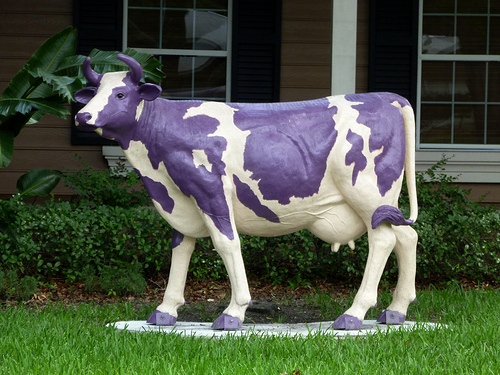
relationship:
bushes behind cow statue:
[11, 15, 82, 115] [64, 44, 435, 343]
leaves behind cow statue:
[11, 15, 82, 115] [64, 44, 435, 343]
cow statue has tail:
[64, 44, 435, 343] [398, 94, 424, 227]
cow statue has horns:
[64, 44, 435, 343] [77, 49, 148, 81]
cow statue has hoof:
[64, 44, 435, 343] [208, 310, 248, 335]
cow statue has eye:
[64, 44, 435, 343] [115, 87, 127, 104]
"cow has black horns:
[64, 44, 435, 343] [77, 49, 148, 81]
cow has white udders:
[64, 44, 435, 343] [306, 204, 367, 260]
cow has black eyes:
[64, 44, 435, 343] [115, 87, 127, 104]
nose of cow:
[72, 108, 93, 123] [64, 44, 435, 343]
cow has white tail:
[64, 44, 435, 343] [398, 94, 424, 227]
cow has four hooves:
[64, 44, 435, 343] [138, 309, 406, 330]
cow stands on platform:
[64, 44, 435, 343] [106, 312, 446, 339]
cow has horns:
[64, 44, 435, 343] [77, 49, 148, 81]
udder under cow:
[306, 204, 367, 260] [64, 44, 435, 343]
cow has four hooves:
[64, 44, 435, 343] [138, 304, 419, 334]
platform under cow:
[106, 312, 446, 339] [64, 44, 435, 343]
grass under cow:
[6, 295, 495, 367] [64, 44, 435, 343]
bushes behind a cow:
[11, 15, 82, 115] [64, 44, 435, 343]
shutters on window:
[74, 7, 165, 42] [119, 3, 497, 88]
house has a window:
[10, 6, 496, 94] [119, 3, 497, 88]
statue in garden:
[64, 44, 435, 343] [4, 5, 500, 375]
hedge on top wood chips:
[3, 193, 169, 275] [35, 282, 155, 305]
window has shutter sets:
[119, 3, 497, 88] [10, 6, 496, 94]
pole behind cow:
[328, 0, 357, 96] [64, 44, 435, 343]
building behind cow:
[10, 6, 496, 94] [64, 44, 435, 343]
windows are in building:
[119, 3, 497, 88] [10, 6, 496, 94]